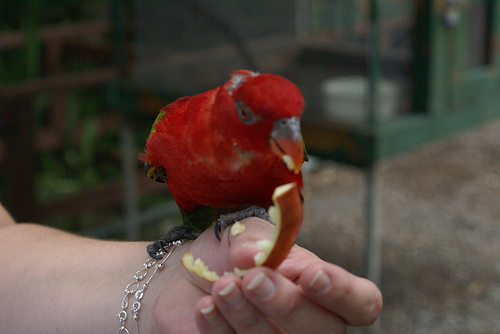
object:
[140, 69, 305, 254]
bird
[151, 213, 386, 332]
hand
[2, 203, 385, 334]
person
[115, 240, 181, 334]
bracelet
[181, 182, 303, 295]
red apple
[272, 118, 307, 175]
beak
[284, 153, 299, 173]
food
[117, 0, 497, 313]
bird cage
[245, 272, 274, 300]
fingernail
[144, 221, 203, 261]
claw foot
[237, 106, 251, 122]
right eye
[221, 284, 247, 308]
fingernail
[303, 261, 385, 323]
finger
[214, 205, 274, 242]
talons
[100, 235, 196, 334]
wrist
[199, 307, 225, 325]
fingernail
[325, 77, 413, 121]
bowl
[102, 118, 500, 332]
ground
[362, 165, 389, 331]
support leg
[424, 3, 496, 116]
door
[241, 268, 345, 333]
finger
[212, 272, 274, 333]
finger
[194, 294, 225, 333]
finger